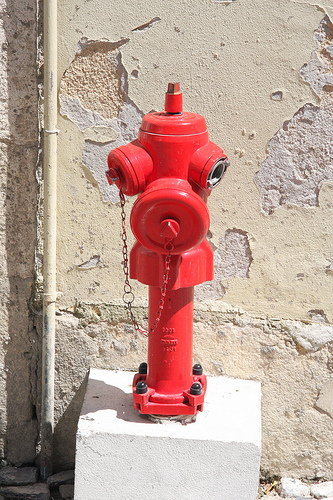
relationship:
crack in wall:
[66, 27, 142, 136] [1, 1, 332, 482]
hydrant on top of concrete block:
[105, 74, 230, 426] [71, 405, 263, 497]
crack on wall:
[66, 27, 142, 136] [56, 0, 332, 483]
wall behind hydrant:
[56, 0, 332, 483] [105, 74, 230, 426]